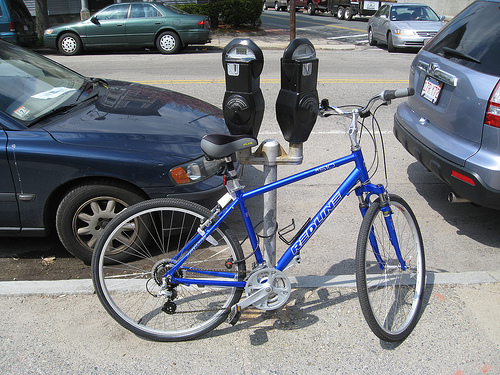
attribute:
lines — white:
[122, 57, 408, 101]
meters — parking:
[220, 36, 319, 143]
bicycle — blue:
[83, 136, 437, 344]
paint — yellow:
[162, 70, 416, 97]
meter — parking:
[269, 34, 321, 158]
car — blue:
[0, 37, 247, 261]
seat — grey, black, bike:
[193, 126, 269, 159]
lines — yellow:
[127, 79, 412, 84]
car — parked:
[38, 2, 222, 57]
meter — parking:
[217, 33, 321, 158]